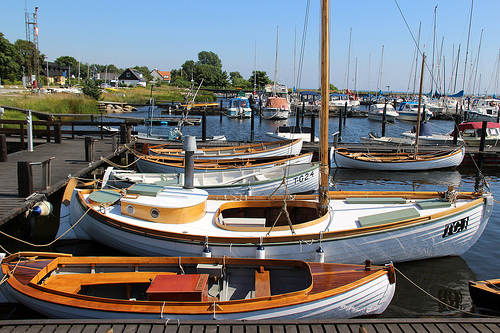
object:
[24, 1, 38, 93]
metal tower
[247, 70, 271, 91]
trees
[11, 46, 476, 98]
distance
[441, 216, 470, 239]
sign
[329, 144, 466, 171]
boat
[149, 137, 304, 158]
boat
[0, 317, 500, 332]
pier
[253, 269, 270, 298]
bench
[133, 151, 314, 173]
boat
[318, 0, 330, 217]
mast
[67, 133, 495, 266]
sailboats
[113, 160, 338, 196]
boat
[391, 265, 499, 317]
rope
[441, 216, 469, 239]
tgi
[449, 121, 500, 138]
maroon cover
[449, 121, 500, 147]
boat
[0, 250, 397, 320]
boat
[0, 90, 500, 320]
harbor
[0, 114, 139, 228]
pier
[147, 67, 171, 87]
house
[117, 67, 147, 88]
house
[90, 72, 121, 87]
house